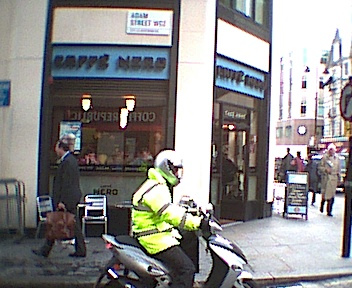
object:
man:
[128, 145, 211, 288]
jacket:
[127, 167, 203, 256]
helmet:
[154, 149, 185, 187]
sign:
[49, 42, 171, 79]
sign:
[213, 51, 268, 100]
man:
[30, 138, 87, 259]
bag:
[44, 208, 78, 242]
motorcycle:
[93, 195, 257, 287]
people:
[281, 147, 293, 187]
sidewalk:
[220, 209, 352, 281]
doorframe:
[210, 84, 266, 222]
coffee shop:
[35, 38, 273, 237]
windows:
[47, 102, 171, 165]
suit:
[45, 151, 85, 254]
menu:
[287, 173, 307, 215]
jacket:
[282, 154, 294, 169]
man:
[318, 142, 341, 218]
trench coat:
[318, 154, 342, 199]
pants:
[150, 233, 197, 288]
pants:
[37, 207, 86, 254]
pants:
[320, 196, 334, 213]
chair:
[36, 195, 54, 239]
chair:
[81, 193, 108, 241]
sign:
[0, 79, 12, 107]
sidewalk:
[1, 233, 139, 285]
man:
[303, 154, 319, 204]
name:
[53, 54, 166, 71]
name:
[217, 65, 264, 91]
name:
[93, 188, 118, 196]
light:
[80, 97, 92, 110]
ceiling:
[53, 95, 167, 113]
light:
[125, 98, 135, 111]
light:
[121, 107, 129, 117]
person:
[293, 151, 305, 172]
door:
[222, 121, 246, 222]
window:
[212, 101, 222, 174]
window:
[249, 110, 257, 167]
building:
[275, 46, 323, 158]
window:
[301, 100, 307, 115]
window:
[302, 77, 306, 88]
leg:
[32, 232, 56, 256]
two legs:
[156, 243, 192, 288]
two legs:
[69, 222, 89, 258]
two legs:
[326, 200, 334, 218]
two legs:
[311, 189, 316, 205]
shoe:
[68, 250, 87, 258]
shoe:
[31, 248, 49, 258]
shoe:
[320, 207, 324, 213]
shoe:
[327, 212, 333, 217]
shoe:
[311, 203, 315, 207]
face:
[170, 165, 182, 179]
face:
[329, 149, 335, 156]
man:
[132, 147, 154, 167]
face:
[140, 152, 147, 158]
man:
[80, 149, 99, 165]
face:
[55, 143, 60, 156]